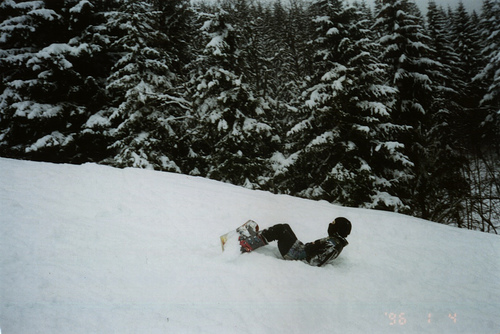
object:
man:
[220, 215, 354, 267]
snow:
[0, 158, 498, 332]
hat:
[335, 217, 351, 234]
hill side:
[298, 154, 497, 327]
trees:
[0, 0, 90, 155]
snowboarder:
[219, 215, 352, 265]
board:
[213, 218, 260, 253]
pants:
[258, 221, 296, 253]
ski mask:
[327, 222, 342, 238]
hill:
[1, 155, 476, 331]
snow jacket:
[278, 238, 350, 265]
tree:
[277, 0, 417, 211]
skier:
[236, 217, 353, 269]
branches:
[471, 166, 497, 236]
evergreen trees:
[100, 3, 198, 170]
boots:
[238, 233, 268, 254]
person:
[239, 214, 352, 266]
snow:
[335, 116, 420, 211]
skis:
[217, 215, 267, 250]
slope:
[0, 157, 492, 333]